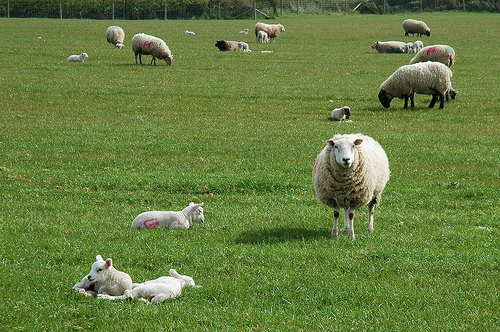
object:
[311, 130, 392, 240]
sheep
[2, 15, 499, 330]
field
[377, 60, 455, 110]
sheep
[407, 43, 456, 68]
sheep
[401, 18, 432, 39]
sheep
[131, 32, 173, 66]
sheep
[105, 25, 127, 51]
sheep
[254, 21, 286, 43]
sheep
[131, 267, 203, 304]
lamb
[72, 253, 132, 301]
lamb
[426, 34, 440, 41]
grass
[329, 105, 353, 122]
lamb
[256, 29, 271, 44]
lamb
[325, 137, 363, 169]
head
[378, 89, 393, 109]
face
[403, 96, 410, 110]
leg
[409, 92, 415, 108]
leg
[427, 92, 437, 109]
leg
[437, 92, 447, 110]
leg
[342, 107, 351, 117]
face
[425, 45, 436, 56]
letter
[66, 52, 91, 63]
flock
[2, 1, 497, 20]
fence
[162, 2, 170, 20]
post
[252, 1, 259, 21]
post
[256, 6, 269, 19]
brace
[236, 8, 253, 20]
brace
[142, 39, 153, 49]
letter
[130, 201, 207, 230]
lamb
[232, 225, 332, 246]
shadow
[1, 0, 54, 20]
bushes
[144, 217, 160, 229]
marking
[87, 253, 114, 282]
head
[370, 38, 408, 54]
sheep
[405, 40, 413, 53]
lamb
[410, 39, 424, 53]
lamb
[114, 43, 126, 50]
head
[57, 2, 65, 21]
post